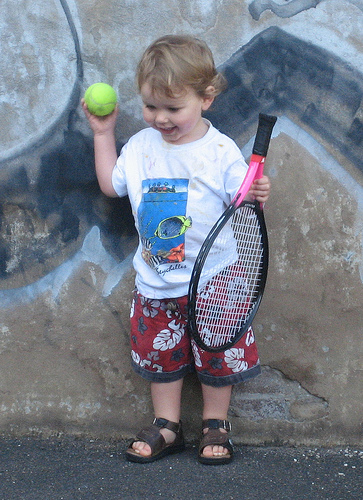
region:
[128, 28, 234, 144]
head of a person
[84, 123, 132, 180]
arm of a person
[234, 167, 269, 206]
arm of a person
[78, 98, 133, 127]
hand of a person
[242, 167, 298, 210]
hand of a person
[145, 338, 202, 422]
leg of a person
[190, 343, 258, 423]
leg of a person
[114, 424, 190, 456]
feet of a person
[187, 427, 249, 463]
feet of a person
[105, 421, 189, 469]
a feet of a person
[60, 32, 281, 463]
Toddler with a tennis racket.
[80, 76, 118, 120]
Yellow tennis ball with stain.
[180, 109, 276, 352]
Black tennis racket with pink handle.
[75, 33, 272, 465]
Small child with brown shoes.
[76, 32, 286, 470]
Boy wearing white tee shirt with fish on it.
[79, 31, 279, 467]
Child holding a tennis ball with Hawaiian shorts on.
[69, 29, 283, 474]
Toddler holding a tennis ball, and racket.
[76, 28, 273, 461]
Child with ball smiling.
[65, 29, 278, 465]
Boy standing against wall hold tennis racket.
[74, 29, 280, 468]
Boy with blonde hair wearing fish tee shirt.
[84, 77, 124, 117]
lime green tennis ball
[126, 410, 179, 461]
brown sandles on foot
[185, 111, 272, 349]
pink and black racket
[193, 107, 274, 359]
black and pink tennis racket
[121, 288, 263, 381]
red and flowered shorts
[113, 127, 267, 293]
short sleeved white tee shirt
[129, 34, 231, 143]
little boy with blonde hair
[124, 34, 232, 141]
young boy with blonde hair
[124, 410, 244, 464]
pair of brown sandles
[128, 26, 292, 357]
little boy holding tennis racket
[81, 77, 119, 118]
The ball is yellow.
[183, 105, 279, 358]
The racket is black and red.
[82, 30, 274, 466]
The child is going to play tennis.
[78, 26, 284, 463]
The child is smiling.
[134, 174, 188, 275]
The picture on the shirt has fish.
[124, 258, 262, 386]
The shorts are floral print.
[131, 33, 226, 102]
The hair is blonde.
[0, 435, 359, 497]
The ground is hard.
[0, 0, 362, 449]
The wall is stone.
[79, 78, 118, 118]
The ball is for tennis.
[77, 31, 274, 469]
a boy holding racket and ball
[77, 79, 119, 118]
a ball the boy is holding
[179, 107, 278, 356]
a racket the boy is holding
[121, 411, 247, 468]
sandals the boy is wearing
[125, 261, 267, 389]
shorts the boy is wearing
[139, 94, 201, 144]
a facial expression of the boy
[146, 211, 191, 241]
a print on the boy's shirt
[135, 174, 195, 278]
a print on the boy's shirt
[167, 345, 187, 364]
a print on the boy's shorts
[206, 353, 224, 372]
a flower print on shorts